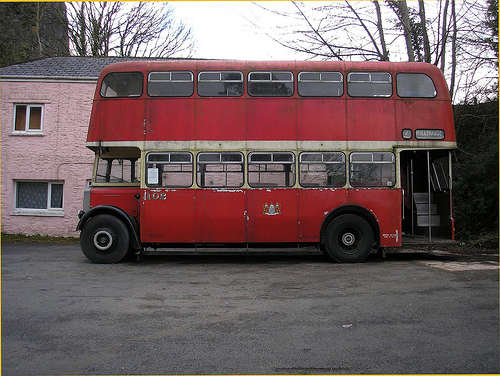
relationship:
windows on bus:
[142, 145, 398, 192] [77, 52, 462, 265]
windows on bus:
[144, 67, 439, 104] [77, 52, 462, 265]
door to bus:
[399, 150, 449, 242] [77, 52, 462, 265]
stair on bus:
[412, 183, 440, 227] [77, 52, 462, 265]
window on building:
[12, 104, 48, 134] [0, 52, 332, 241]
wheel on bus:
[79, 213, 131, 265] [77, 52, 462, 265]